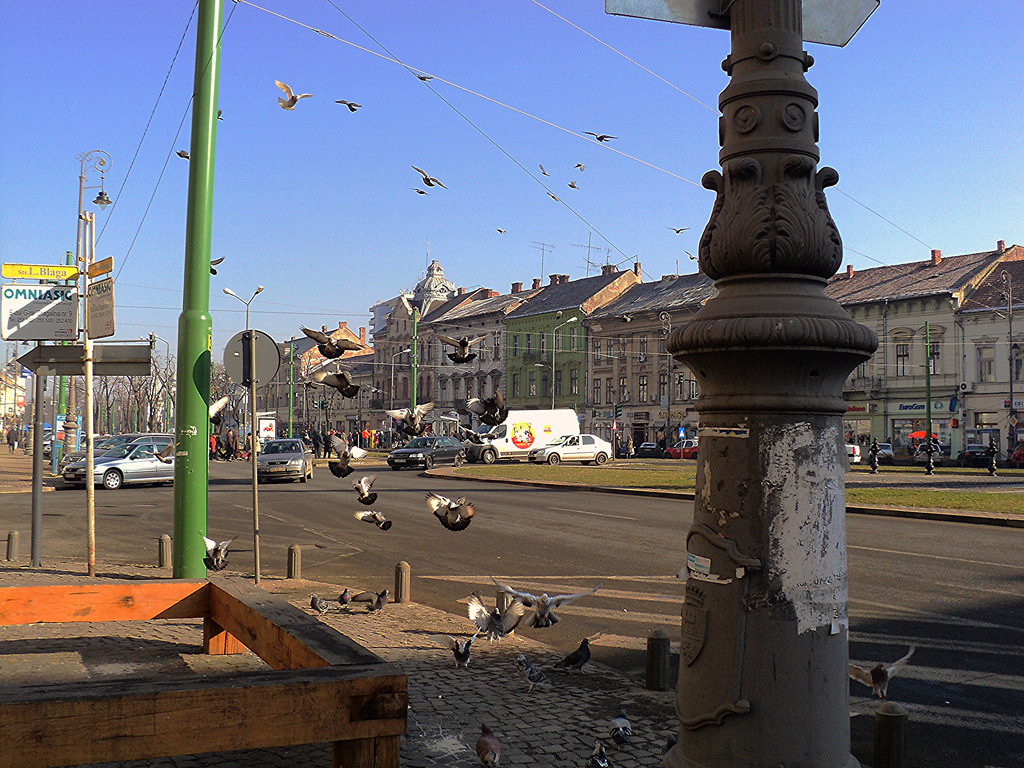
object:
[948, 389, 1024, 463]
wall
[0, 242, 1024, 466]
building